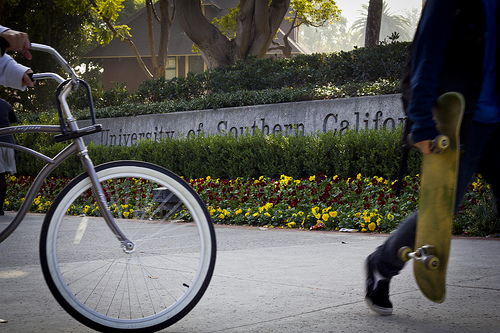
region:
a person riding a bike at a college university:
[1, 21, 218, 331]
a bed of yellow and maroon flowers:
[226, 176, 395, 221]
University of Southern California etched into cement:
[99, 102, 403, 152]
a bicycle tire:
[37, 157, 219, 332]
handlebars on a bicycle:
[26, 41, 79, 88]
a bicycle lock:
[50, 77, 103, 142]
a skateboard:
[399, 85, 464, 303]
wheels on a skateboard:
[395, 244, 441, 272]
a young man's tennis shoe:
[360, 254, 396, 319]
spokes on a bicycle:
[96, 262, 158, 303]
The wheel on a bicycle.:
[31, 143, 234, 326]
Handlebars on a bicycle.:
[0, 25, 105, 110]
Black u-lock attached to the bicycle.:
[42, 70, 107, 150]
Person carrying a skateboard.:
[395, 71, 472, 311]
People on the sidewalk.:
[0, 190, 496, 325]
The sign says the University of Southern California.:
[85, 95, 416, 150]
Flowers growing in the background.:
[220, 170, 385, 225]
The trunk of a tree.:
[132, 27, 178, 102]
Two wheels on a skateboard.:
[395, 236, 462, 268]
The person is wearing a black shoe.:
[349, 240, 402, 323]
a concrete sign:
[66, 90, 404, 150]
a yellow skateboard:
[381, 86, 468, 308]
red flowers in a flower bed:
[176, 177, 381, 222]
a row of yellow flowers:
[215, 205, 390, 225]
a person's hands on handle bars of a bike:
[0, 15, 71, 104]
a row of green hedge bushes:
[13, 119, 380, 190]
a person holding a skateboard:
[364, 21, 476, 303]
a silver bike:
[1, 71, 99, 231]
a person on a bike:
[0, 14, 105, 210]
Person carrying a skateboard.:
[357, 2, 484, 318]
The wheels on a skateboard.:
[410, 106, 462, 290]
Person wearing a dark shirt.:
[401, 2, 493, 139]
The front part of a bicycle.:
[12, 24, 242, 330]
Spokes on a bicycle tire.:
[51, 172, 226, 332]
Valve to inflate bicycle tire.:
[176, 279, 198, 291]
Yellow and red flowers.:
[217, 170, 388, 228]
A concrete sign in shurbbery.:
[78, 87, 399, 144]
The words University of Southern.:
[86, 120, 315, 151]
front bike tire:
[38, 152, 203, 331]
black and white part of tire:
[164, 177, 255, 274]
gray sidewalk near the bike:
[258, 233, 334, 302]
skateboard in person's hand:
[390, 103, 483, 290]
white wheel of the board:
[433, 133, 457, 158]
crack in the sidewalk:
[278, 276, 330, 309]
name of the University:
[93, 114, 406, 158]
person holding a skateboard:
[386, 3, 493, 283]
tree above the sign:
[196, 10, 304, 63]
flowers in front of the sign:
[257, 161, 353, 236]